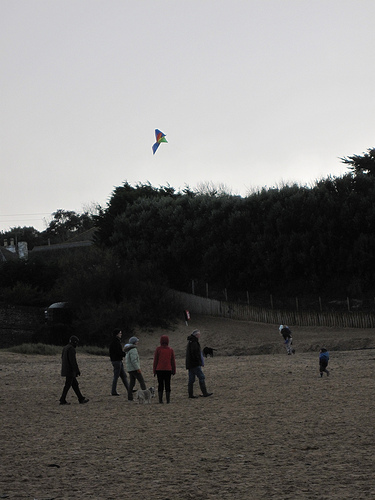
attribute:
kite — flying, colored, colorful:
[146, 129, 164, 152]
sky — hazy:
[194, 60, 217, 78]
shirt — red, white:
[155, 349, 171, 369]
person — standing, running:
[312, 347, 328, 373]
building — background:
[32, 294, 67, 317]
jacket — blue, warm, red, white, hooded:
[312, 349, 330, 361]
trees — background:
[137, 198, 199, 270]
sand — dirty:
[241, 374, 253, 388]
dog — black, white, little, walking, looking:
[285, 334, 296, 353]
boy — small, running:
[317, 347, 329, 376]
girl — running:
[154, 340, 183, 406]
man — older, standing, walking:
[51, 337, 87, 405]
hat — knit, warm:
[188, 333, 193, 340]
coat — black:
[179, 345, 196, 364]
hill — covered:
[59, 217, 97, 246]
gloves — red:
[117, 346, 124, 350]